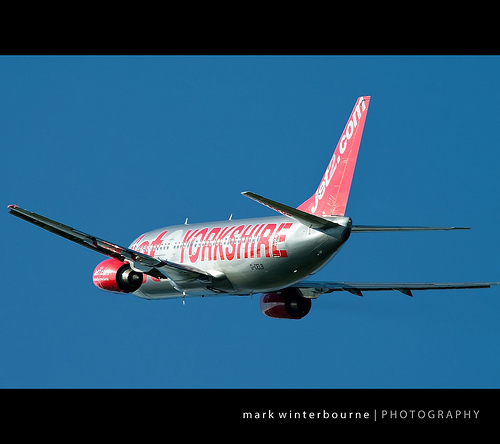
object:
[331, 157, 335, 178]
colour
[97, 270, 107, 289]
colour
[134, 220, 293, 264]
letters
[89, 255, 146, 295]
engine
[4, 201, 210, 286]
wing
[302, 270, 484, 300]
wing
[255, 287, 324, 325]
engine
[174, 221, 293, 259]
name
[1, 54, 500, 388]
skies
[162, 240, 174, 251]
door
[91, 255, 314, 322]
engine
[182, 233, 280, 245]
red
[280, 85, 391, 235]
red tail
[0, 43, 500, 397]
air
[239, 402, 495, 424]
letters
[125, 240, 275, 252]
windows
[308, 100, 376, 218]
letters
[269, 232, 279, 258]
door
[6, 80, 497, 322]
airplane